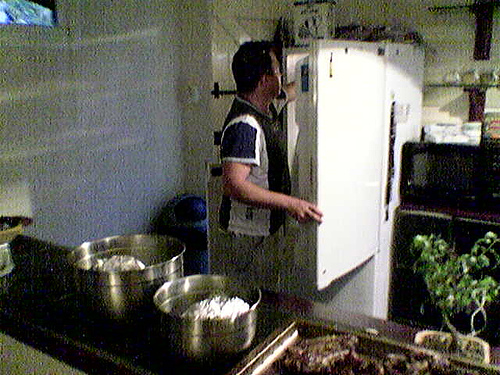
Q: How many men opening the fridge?
A: One.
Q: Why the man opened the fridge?
A: To check on food.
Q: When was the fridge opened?
A: Just now.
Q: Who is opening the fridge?
A: The man.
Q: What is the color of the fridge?
A: White.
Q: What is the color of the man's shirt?
A: Black and white.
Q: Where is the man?
A: In the kitchen.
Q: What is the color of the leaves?
A: Green.